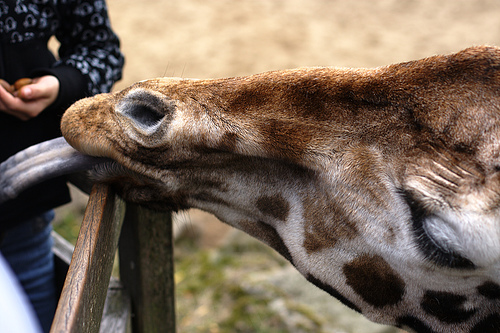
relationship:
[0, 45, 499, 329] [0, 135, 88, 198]
giraffe has tongue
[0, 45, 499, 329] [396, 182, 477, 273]
giraffe has eye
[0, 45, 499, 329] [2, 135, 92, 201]
giraffe has tongue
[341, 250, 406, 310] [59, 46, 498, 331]
spot on face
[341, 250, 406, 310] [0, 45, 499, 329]
spot on giraffe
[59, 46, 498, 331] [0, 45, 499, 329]
face on giraffe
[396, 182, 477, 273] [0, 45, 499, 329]
eye on giraffe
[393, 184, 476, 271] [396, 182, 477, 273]
lashes on eye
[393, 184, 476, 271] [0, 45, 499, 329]
lashes on giraffe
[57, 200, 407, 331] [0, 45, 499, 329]
grass under giraffe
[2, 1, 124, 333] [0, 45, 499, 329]
person feeding giraffe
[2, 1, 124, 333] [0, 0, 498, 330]
person at zoo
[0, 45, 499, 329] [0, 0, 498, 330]
giraffe at zoo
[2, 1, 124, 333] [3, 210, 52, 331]
person wearing jeans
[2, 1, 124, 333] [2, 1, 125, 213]
person wearing sweater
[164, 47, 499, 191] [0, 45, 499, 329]
forehead on giraffe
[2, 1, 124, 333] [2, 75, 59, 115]
person has hand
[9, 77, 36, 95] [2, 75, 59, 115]
food in hand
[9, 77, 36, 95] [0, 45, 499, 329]
food for giraffe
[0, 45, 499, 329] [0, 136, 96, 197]
giraffe has tongue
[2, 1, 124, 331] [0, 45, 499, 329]
person standing near giraffe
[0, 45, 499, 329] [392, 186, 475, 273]
giraffe has eyelashes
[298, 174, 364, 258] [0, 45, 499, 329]
spot on giraffe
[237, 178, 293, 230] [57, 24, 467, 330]
spot on giraffe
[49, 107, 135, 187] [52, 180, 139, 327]
mouth on wood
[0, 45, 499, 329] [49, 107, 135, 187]
giraffe has mouth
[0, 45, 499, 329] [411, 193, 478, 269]
giraffe has eyeball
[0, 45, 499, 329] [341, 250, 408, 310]
giraffe has spot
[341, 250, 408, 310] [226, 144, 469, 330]
spot on face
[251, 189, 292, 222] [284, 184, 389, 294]
spot on face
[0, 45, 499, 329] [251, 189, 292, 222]
giraffe has spot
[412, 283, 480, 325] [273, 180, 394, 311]
spot on face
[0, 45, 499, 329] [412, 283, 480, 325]
giraffe has spot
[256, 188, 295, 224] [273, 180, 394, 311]
spot on face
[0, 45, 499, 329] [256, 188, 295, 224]
giraffe has spot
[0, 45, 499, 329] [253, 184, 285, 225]
giraffe has spot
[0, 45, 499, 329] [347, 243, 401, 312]
giraffe has spot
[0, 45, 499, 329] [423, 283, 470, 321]
giraffe has spot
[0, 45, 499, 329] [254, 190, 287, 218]
giraffe has spot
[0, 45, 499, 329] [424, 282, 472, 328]
giraffe has spot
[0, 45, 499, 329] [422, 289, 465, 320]
giraffe has spot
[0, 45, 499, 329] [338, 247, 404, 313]
giraffe has spot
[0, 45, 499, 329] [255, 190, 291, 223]
giraffe has spot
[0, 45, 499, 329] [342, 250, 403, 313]
giraffe has spot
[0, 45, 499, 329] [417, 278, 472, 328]
giraffe has spot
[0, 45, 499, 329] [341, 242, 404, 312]
giraffe has spot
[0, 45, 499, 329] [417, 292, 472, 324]
giraffe has spot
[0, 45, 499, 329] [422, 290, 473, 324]
giraffe has spot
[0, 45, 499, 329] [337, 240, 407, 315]
giraffe has spot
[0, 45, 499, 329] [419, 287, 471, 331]
giraffe has spot